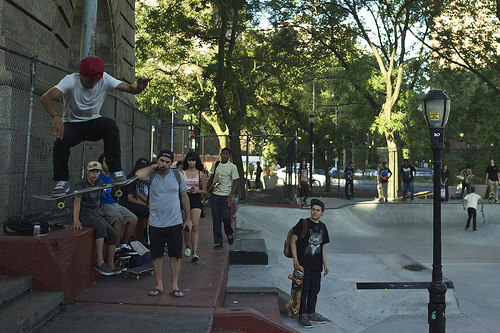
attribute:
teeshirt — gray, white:
[59, 78, 189, 241]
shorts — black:
[147, 221, 183, 266]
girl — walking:
[176, 145, 202, 269]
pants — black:
[42, 121, 138, 177]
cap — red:
[72, 56, 113, 89]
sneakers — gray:
[43, 166, 135, 195]